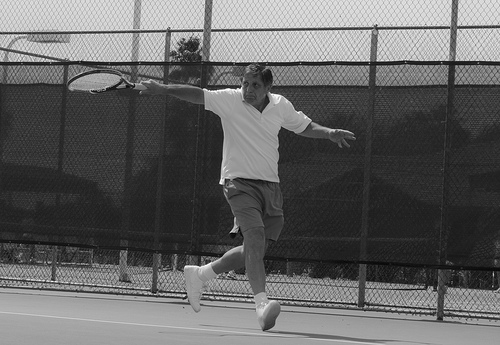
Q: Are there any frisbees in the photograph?
A: No, there are no frisbees.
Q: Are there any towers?
A: No, there are no towers.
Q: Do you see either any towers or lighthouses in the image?
A: No, there are no towers or lighthouses.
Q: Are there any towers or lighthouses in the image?
A: No, there are no towers or lighthouses.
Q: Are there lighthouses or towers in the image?
A: No, there are no towers or lighthouses.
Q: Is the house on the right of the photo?
A: Yes, the house is on the right of the image.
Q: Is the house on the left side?
A: No, the house is on the right of the image.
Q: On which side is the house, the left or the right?
A: The house is on the right of the image.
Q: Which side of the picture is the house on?
A: The house is on the right of the image.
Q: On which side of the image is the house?
A: The house is on the right of the image.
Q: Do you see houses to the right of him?
A: Yes, there is a house to the right of the man.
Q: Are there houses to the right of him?
A: Yes, there is a house to the right of the man.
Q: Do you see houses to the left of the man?
A: No, the house is to the right of the man.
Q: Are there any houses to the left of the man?
A: No, the house is to the right of the man.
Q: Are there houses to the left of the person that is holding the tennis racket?
A: No, the house is to the right of the man.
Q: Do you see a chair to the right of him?
A: No, there is a house to the right of the man.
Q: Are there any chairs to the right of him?
A: No, there is a house to the right of the man.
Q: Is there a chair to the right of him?
A: No, there is a house to the right of the man.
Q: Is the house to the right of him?
A: Yes, the house is to the right of a man.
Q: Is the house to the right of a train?
A: No, the house is to the right of a man.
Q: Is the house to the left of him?
A: No, the house is to the right of the man.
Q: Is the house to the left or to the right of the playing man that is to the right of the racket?
A: The house is to the right of the man.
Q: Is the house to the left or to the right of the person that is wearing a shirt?
A: The house is to the right of the man.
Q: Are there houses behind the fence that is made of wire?
A: Yes, there is a house behind the fence.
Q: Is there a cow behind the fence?
A: No, there is a house behind the fence.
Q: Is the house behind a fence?
A: Yes, the house is behind a fence.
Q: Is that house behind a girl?
A: No, the house is behind a fence.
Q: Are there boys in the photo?
A: No, there are no boys.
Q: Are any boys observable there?
A: No, there are no boys.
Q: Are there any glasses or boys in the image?
A: No, there are no boys or glasses.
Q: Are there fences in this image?
A: Yes, there is a fence.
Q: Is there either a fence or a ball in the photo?
A: Yes, there is a fence.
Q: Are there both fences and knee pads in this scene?
A: No, there is a fence but no knee pads.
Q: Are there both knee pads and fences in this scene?
A: No, there is a fence but no knee pads.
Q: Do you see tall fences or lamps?
A: Yes, there is a tall fence.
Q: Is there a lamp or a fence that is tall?
A: Yes, the fence is tall.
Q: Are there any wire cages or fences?
A: Yes, there is a wire fence.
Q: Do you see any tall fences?
A: Yes, there is a tall fence.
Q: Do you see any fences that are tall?
A: Yes, there is a fence that is tall.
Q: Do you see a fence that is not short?
A: Yes, there is a tall fence.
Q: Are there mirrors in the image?
A: No, there are no mirrors.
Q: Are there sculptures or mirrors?
A: No, there are no mirrors or sculptures.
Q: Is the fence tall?
A: Yes, the fence is tall.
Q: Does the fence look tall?
A: Yes, the fence is tall.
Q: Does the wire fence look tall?
A: Yes, the fence is tall.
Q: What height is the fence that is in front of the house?
A: The fence is tall.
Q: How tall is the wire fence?
A: The fence is tall.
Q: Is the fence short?
A: No, the fence is tall.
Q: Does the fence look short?
A: No, the fence is tall.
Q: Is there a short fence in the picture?
A: No, there is a fence but it is tall.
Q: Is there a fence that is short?
A: No, there is a fence but it is tall.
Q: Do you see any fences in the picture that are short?
A: No, there is a fence but it is tall.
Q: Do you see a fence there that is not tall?
A: No, there is a fence but it is tall.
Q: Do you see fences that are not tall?
A: No, there is a fence but it is tall.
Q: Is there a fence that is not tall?
A: No, there is a fence but it is tall.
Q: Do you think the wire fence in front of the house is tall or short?
A: The fence is tall.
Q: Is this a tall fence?
A: Yes, this is a tall fence.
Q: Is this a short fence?
A: No, this is a tall fence.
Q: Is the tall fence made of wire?
A: Yes, the fence is made of wire.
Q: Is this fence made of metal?
A: No, the fence is made of wire.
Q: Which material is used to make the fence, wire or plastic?
A: The fence is made of wire.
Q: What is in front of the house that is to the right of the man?
A: The fence is in front of the house.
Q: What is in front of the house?
A: The fence is in front of the house.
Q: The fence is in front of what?
A: The fence is in front of the house.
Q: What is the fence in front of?
A: The fence is in front of the house.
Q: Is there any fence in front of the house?
A: Yes, there is a fence in front of the house.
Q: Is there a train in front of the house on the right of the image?
A: No, there is a fence in front of the house.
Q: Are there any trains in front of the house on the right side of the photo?
A: No, there is a fence in front of the house.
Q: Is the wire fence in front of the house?
A: Yes, the fence is in front of the house.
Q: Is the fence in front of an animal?
A: No, the fence is in front of the house.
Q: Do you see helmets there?
A: No, there are no helmets.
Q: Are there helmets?
A: No, there are no helmets.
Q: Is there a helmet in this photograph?
A: No, there are no helmets.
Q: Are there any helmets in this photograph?
A: No, there are no helmets.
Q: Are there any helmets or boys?
A: No, there are no helmets or boys.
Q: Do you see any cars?
A: No, there are no cars.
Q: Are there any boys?
A: No, there are no boys.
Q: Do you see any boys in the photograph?
A: No, there are no boys.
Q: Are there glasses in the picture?
A: No, there are no glasses.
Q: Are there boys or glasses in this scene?
A: No, there are no glasses or boys.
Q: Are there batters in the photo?
A: No, there are no batters.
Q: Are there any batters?
A: No, there are no batters.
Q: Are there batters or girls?
A: No, there are no batters or girls.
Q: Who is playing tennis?
A: The man is playing tennis.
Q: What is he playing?
A: The man is playing tennis.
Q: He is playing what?
A: The man is playing tennis.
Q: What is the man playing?
A: The man is playing tennis.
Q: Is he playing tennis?
A: Yes, the man is playing tennis.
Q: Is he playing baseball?
A: No, the man is playing tennis.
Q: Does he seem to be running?
A: Yes, the man is running.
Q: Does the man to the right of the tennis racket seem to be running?
A: Yes, the man is running.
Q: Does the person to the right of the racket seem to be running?
A: Yes, the man is running.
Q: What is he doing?
A: The man is running.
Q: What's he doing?
A: The man is running.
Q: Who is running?
A: The man is running.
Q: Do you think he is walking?
A: No, the man is running.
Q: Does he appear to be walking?
A: No, the man is running.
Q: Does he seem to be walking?
A: No, the man is running.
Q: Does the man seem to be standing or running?
A: The man is running.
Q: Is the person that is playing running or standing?
A: The man is running.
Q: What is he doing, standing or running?
A: The man is running.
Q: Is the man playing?
A: Yes, the man is playing.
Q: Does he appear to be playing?
A: Yes, the man is playing.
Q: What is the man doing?
A: The man is playing.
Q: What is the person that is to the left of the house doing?
A: The man is playing.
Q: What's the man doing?
A: The man is playing.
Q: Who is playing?
A: The man is playing.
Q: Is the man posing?
A: No, the man is playing.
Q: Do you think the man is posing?
A: No, the man is playing.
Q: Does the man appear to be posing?
A: No, the man is playing.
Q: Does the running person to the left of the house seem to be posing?
A: No, the man is playing.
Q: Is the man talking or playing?
A: The man is playing.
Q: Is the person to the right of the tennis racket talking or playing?
A: The man is playing.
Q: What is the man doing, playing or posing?
A: The man is playing.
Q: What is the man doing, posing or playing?
A: The man is playing.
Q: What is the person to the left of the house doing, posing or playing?
A: The man is playing.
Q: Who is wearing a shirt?
A: The man is wearing a shirt.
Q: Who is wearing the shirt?
A: The man is wearing a shirt.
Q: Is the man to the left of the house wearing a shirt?
A: Yes, the man is wearing a shirt.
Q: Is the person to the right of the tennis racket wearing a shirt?
A: Yes, the man is wearing a shirt.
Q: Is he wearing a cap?
A: No, the man is wearing a shirt.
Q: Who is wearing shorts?
A: The man is wearing shorts.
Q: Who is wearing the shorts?
A: The man is wearing shorts.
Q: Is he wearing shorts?
A: Yes, the man is wearing shorts.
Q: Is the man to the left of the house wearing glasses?
A: No, the man is wearing shorts.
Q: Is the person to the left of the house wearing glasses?
A: No, the man is wearing shorts.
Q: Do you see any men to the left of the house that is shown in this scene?
A: Yes, there is a man to the left of the house.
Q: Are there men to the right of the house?
A: No, the man is to the left of the house.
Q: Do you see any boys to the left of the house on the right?
A: No, there is a man to the left of the house.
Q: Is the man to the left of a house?
A: Yes, the man is to the left of a house.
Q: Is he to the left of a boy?
A: No, the man is to the left of a house.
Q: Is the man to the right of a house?
A: No, the man is to the left of a house.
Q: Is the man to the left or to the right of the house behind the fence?
A: The man is to the left of the house.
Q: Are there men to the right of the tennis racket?
A: Yes, there is a man to the right of the tennis racket.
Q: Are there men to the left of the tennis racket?
A: No, the man is to the right of the tennis racket.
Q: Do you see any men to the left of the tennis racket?
A: No, the man is to the right of the tennis racket.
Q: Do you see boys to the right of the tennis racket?
A: No, there is a man to the right of the tennis racket.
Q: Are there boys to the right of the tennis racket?
A: No, there is a man to the right of the tennis racket.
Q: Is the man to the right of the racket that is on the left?
A: Yes, the man is to the right of the racket.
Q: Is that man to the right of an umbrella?
A: No, the man is to the right of the racket.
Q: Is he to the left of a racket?
A: No, the man is to the right of a racket.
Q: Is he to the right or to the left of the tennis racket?
A: The man is to the right of the tennis racket.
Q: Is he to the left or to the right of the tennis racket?
A: The man is to the right of the tennis racket.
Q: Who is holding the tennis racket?
A: The man is holding the racket.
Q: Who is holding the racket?
A: The man is holding the racket.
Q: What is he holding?
A: The man is holding the racket.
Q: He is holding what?
A: The man is holding the racket.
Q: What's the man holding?
A: The man is holding the racket.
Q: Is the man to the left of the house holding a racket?
A: Yes, the man is holding a racket.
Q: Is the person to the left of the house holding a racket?
A: Yes, the man is holding a racket.